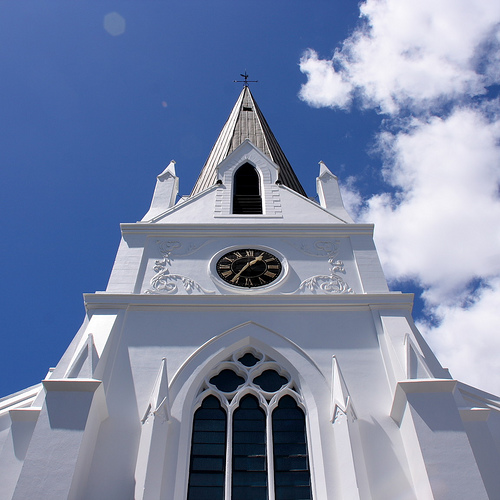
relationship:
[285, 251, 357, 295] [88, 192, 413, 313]
design on wall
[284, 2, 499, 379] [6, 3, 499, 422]
clouds in sky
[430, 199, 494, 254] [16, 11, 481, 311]
clouds in sky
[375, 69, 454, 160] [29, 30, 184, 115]
clouds in sky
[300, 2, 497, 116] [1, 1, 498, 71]
clouds in sky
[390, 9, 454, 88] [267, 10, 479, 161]
white clouds in sky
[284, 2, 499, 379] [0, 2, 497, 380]
clouds in sky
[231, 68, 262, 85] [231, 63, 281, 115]
vane on top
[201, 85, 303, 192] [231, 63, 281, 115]
roof has top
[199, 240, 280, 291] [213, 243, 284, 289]
time on clock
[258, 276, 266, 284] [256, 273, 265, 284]
five for five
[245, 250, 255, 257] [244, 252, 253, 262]
number twelve for numeral